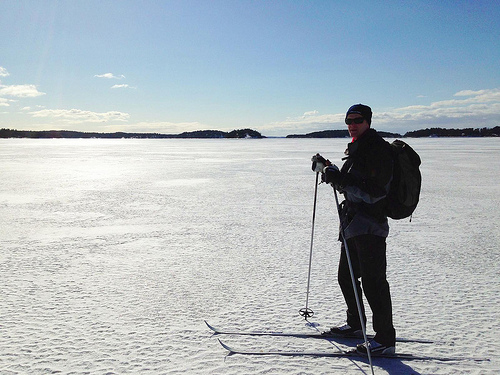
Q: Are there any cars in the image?
A: No, there are no cars.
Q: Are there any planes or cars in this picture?
A: No, there are no cars or planes.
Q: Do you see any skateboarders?
A: No, there are no skateboarders.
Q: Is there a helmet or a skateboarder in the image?
A: No, there are no skateboarders or helmets.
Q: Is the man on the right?
A: Yes, the man is on the right of the image.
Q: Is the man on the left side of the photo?
A: No, the man is on the right of the image.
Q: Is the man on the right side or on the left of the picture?
A: The man is on the right of the image.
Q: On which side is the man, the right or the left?
A: The man is on the right of the image.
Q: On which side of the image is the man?
A: The man is on the right of the image.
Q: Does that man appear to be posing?
A: Yes, the man is posing.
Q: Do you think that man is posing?
A: Yes, the man is posing.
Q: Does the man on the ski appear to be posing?
A: Yes, the man is posing.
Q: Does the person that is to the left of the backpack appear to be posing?
A: Yes, the man is posing.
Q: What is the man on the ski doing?
A: The man is posing.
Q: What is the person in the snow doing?
A: The man is posing.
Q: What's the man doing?
A: The man is posing.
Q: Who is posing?
A: The man is posing.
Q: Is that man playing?
A: No, the man is posing.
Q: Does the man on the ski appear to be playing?
A: No, the man is posing.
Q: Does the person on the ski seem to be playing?
A: No, the man is posing.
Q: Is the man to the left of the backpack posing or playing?
A: The man is posing.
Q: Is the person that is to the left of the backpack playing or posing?
A: The man is posing.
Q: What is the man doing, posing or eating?
A: The man is posing.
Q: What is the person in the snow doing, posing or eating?
A: The man is posing.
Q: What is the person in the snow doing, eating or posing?
A: The man is posing.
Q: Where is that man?
A: The man is in the snow.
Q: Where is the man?
A: The man is in the snow.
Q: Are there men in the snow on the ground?
A: Yes, there is a man in the snow.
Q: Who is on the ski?
A: The man is on the ski.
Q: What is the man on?
A: The man is on the ski.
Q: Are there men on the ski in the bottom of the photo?
A: Yes, there is a man on the ski.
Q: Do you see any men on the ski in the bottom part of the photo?
A: Yes, there is a man on the ski.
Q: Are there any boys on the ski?
A: No, there is a man on the ski.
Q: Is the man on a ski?
A: Yes, the man is on a ski.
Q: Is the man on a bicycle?
A: No, the man is on a ski.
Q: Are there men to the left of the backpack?
A: Yes, there is a man to the left of the backpack.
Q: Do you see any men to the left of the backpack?
A: Yes, there is a man to the left of the backpack.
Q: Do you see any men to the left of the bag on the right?
A: Yes, there is a man to the left of the backpack.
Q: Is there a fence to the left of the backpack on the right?
A: No, there is a man to the left of the backpack.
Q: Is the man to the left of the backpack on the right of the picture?
A: Yes, the man is to the left of the backpack.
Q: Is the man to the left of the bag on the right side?
A: Yes, the man is to the left of the backpack.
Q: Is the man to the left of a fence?
A: No, the man is to the left of the backpack.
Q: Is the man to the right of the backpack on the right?
A: No, the man is to the left of the backpack.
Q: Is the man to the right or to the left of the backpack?
A: The man is to the left of the backpack.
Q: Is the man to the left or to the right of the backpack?
A: The man is to the left of the backpack.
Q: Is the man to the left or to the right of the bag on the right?
A: The man is to the left of the backpack.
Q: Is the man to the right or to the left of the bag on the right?
A: The man is to the left of the backpack.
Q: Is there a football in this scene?
A: No, there are no footballs.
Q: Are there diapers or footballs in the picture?
A: No, there are no footballs or diapers.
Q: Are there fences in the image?
A: No, there are no fences.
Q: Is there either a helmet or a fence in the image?
A: No, there are no fences or helmets.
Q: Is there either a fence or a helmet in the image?
A: No, there are no fences or helmets.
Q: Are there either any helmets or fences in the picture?
A: No, there are no fences or helmets.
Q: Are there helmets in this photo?
A: No, there are no helmets.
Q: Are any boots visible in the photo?
A: Yes, there are boots.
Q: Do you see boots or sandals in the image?
A: Yes, there are boots.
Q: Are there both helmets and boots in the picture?
A: No, there are boots but no helmets.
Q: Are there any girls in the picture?
A: No, there are no girls.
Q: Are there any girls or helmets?
A: No, there are no girls or helmets.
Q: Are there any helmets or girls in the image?
A: No, there are no girls or helmets.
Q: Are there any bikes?
A: No, there are no bikes.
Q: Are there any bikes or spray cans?
A: No, there are no bikes or spray cans.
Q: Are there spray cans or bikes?
A: No, there are no bikes or spray cans.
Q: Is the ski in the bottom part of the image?
A: Yes, the ski is in the bottom of the image.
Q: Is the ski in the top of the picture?
A: No, the ski is in the bottom of the image.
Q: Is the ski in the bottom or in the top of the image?
A: The ski is in the bottom of the image.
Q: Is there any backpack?
A: Yes, there is a backpack.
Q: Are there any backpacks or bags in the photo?
A: Yes, there is a backpack.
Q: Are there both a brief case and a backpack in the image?
A: No, there is a backpack but no briefcases.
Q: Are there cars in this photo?
A: No, there are no cars.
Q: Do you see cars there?
A: No, there are no cars.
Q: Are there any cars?
A: No, there are no cars.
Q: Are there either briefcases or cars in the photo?
A: No, there are no cars or briefcases.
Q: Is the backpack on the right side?
A: Yes, the backpack is on the right of the image.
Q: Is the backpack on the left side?
A: No, the backpack is on the right of the image.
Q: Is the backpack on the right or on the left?
A: The backpack is on the right of the image.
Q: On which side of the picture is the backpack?
A: The backpack is on the right of the image.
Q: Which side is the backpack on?
A: The backpack is on the right of the image.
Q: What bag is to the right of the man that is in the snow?
A: The bag is a backpack.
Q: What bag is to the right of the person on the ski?
A: The bag is a backpack.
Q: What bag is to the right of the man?
A: The bag is a backpack.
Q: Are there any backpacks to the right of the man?
A: Yes, there is a backpack to the right of the man.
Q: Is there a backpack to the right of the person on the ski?
A: Yes, there is a backpack to the right of the man.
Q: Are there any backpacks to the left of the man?
A: No, the backpack is to the right of the man.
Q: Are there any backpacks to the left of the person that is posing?
A: No, the backpack is to the right of the man.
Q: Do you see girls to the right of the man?
A: No, there is a backpack to the right of the man.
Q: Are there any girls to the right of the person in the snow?
A: No, there is a backpack to the right of the man.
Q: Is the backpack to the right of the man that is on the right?
A: Yes, the backpack is to the right of the man.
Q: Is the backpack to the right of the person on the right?
A: Yes, the backpack is to the right of the man.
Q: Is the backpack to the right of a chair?
A: No, the backpack is to the right of the man.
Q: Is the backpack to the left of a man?
A: No, the backpack is to the right of a man.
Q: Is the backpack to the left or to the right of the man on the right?
A: The backpack is to the right of the man.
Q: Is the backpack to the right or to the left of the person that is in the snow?
A: The backpack is to the right of the man.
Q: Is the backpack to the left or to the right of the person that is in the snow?
A: The backpack is to the right of the man.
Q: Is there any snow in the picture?
A: Yes, there is snow.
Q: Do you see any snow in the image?
A: Yes, there is snow.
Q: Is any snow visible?
A: Yes, there is snow.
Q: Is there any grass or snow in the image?
A: Yes, there is snow.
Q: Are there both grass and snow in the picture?
A: No, there is snow but no grass.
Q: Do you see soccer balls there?
A: No, there are no soccer balls.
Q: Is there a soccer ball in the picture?
A: No, there are no soccer balls.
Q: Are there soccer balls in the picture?
A: No, there are no soccer balls.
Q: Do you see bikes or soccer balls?
A: No, there are no soccer balls or bikes.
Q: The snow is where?
A: The snow is on the ground.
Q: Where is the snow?
A: The snow is on the ground.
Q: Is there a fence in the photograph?
A: No, there are no fences.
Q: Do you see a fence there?
A: No, there are no fences.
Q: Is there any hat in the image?
A: Yes, there is a hat.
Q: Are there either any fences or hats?
A: Yes, there is a hat.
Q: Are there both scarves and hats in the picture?
A: No, there is a hat but no scarves.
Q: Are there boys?
A: No, there are no boys.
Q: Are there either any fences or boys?
A: No, there are no boys or fences.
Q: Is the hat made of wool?
A: Yes, the hat is made of wool.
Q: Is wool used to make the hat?
A: Yes, the hat is made of wool.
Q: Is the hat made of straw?
A: No, the hat is made of wool.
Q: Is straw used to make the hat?
A: No, the hat is made of wool.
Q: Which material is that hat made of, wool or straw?
A: The hat is made of wool.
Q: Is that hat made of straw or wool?
A: The hat is made of wool.